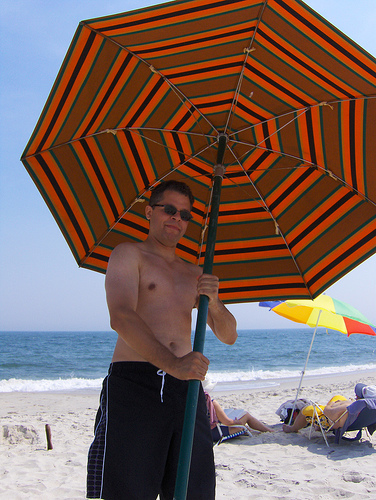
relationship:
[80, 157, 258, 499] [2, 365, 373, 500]
man on beach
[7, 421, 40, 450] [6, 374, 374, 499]
footstep in sand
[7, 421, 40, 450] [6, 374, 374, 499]
footstep on sand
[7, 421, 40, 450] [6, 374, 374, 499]
footstep on top of sand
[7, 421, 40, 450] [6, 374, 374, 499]
footstep all over sand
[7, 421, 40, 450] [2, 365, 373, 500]
footstep on beach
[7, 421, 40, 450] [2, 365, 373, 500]
footstep on top of beach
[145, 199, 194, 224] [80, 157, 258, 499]
glasses on man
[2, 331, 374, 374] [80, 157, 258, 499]
water behind man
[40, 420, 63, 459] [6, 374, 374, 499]
stick in sand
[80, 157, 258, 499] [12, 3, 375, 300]
man holding umbrella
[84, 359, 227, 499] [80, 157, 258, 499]
trunks on man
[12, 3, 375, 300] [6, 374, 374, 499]
umbrella in sand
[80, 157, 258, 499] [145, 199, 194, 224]
man wearing glasses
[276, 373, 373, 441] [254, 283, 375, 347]
person under umbrella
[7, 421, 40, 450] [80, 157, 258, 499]
footstep near man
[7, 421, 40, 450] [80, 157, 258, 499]
footstep close to man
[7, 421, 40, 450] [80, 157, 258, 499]
footstep behind man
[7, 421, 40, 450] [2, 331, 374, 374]
footstep near water